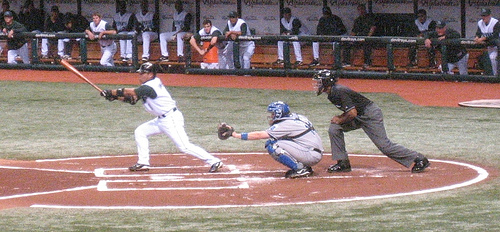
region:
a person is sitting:
[273, 4, 310, 62]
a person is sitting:
[306, 0, 343, 65]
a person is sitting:
[344, 2, 381, 63]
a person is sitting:
[403, 9, 434, 59]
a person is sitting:
[156, 1, 191, 56]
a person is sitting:
[129, 1, 154, 57]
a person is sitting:
[104, 0, 131, 57]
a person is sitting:
[54, 5, 87, 55]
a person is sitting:
[38, 2, 75, 52]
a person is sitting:
[18, 2, 48, 52]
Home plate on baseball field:
[143, 166, 193, 192]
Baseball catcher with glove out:
[208, 91, 328, 183]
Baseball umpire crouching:
[309, 61, 437, 178]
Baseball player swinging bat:
[56, 36, 223, 191]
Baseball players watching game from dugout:
[52, 6, 319, 69]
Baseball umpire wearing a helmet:
[306, 55, 381, 131]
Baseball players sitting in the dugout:
[114, 1, 193, 65]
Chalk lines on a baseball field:
[20, 155, 132, 218]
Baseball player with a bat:
[61, 48, 213, 168]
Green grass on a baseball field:
[6, 87, 85, 153]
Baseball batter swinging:
[101, 62, 225, 173]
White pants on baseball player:
[134, 109, 222, 165]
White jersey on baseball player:
[138, 77, 178, 114]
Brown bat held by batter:
[58, 56, 108, 93]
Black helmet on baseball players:
[138, 57, 157, 76]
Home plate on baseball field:
[151, 167, 184, 182]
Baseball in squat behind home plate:
[215, 97, 328, 177]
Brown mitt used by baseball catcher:
[214, 117, 237, 144]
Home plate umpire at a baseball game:
[313, 67, 430, 174]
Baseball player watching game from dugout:
[221, 9, 256, 69]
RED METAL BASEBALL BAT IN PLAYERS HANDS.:
[55, 53, 107, 97]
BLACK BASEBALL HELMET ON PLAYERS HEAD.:
[132, 58, 157, 72]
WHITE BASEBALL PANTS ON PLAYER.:
[124, 118, 220, 164]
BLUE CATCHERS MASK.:
[262, 101, 291, 125]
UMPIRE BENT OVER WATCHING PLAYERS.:
[314, 62, 438, 179]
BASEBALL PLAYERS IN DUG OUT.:
[2, 2, 499, 52]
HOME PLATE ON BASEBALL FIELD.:
[142, 170, 184, 185]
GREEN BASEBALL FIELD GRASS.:
[415, 204, 487, 226]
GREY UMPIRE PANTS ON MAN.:
[330, 109, 418, 164]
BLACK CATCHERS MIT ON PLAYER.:
[215, 121, 232, 143]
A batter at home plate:
[35, 38, 205, 198]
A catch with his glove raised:
[201, 105, 326, 184]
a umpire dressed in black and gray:
[291, 67, 422, 190]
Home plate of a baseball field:
[122, 162, 213, 211]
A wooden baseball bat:
[50, 45, 129, 99]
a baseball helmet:
[137, 58, 164, 78]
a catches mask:
[263, 100, 287, 119]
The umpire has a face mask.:
[311, 67, 343, 95]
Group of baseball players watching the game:
[125, 10, 315, 68]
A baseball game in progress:
[47, 34, 427, 212]